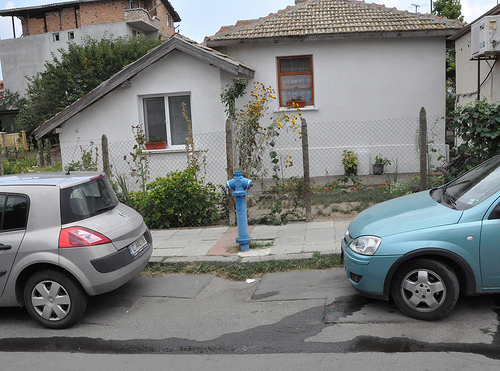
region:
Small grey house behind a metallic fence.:
[55, 16, 460, 198]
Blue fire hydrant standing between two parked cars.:
[220, 165, 265, 260]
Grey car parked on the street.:
[1, 167, 152, 327]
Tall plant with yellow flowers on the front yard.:
[240, 76, 305, 172]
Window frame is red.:
[271, 50, 318, 111]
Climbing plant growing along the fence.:
[437, 96, 497, 174]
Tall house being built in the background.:
[3, 1, 183, 81]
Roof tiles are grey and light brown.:
[231, 5, 462, 35]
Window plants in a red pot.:
[143, 136, 168, 151]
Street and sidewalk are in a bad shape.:
[151, 220, 339, 360]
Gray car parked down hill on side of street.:
[6, 168, 158, 327]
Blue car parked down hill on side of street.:
[336, 138, 498, 323]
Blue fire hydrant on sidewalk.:
[221, 166, 258, 252]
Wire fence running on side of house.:
[252, 115, 359, 219]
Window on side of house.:
[134, 89, 204, 157]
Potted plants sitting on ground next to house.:
[336, 146, 386, 181]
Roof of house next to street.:
[204, 0, 468, 47]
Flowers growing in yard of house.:
[229, 80, 305, 173]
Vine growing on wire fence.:
[437, 103, 497, 180]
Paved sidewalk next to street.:
[158, 220, 332, 262]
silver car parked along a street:
[4, 173, 150, 313]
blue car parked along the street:
[341, 199, 495, 317]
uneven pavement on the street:
[137, 277, 342, 362]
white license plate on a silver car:
[127, 235, 148, 251]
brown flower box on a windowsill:
[145, 140, 165, 148]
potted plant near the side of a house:
[342, 148, 357, 171]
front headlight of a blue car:
[350, 233, 376, 253]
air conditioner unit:
[471, 16, 494, 61]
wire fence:
[311, 125, 409, 146]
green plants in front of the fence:
[150, 177, 211, 222]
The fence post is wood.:
[46, 132, 184, 240]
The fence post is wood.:
[158, 108, 278, 229]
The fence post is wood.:
[273, 105, 363, 232]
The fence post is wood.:
[345, 99, 499, 223]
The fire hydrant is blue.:
[218, 166, 264, 258]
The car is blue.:
[319, 143, 499, 325]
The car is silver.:
[0, 157, 165, 334]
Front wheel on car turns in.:
[322, 145, 499, 326]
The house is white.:
[20, 0, 480, 220]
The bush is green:
[131, 160, 231, 235]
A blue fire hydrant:
[218, 165, 260, 256]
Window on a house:
[270, 49, 320, 114]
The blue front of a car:
[337, 148, 498, 322]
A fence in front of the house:
[0, 103, 499, 227]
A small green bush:
[135, 165, 221, 230]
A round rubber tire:
[19, 266, 90, 331]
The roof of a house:
[205, 1, 465, 48]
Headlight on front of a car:
[344, 231, 384, 261]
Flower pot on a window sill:
[140, 135, 171, 155]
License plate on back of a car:
[127, 231, 152, 259]